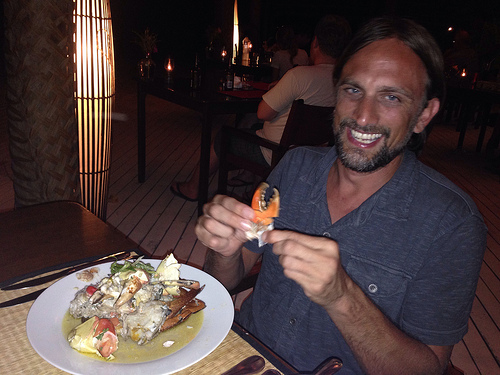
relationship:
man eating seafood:
[196, 31, 481, 373] [238, 173, 284, 249]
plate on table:
[26, 257, 230, 373] [0, 198, 309, 373]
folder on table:
[0, 187, 157, 292] [9, 177, 144, 287]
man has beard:
[196, 31, 481, 373] [331, 121, 403, 173]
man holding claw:
[196, 31, 481, 373] [246, 181, 280, 247]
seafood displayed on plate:
[85, 280, 172, 322] [36, 240, 225, 369]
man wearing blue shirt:
[196, 31, 481, 373] [234, 142, 486, 362]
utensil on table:
[3, 250, 103, 320] [0, 195, 150, 293]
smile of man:
[345, 127, 381, 144] [186, 33, 466, 350]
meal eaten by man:
[62, 244, 200, 361] [174, 20, 463, 267]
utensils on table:
[0, 250, 126, 308] [0, 198, 309, 373]